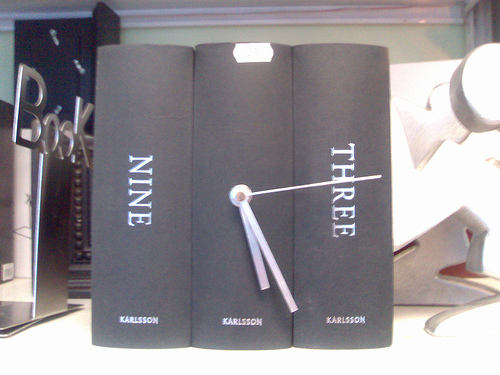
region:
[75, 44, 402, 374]
the clock is black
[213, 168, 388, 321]
the time is 5:25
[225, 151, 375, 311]
the hands are silver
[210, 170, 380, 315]
the clack has hands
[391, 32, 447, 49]
the wall is green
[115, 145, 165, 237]
the nine is silver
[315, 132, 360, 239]
the three is silver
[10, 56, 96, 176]
the word book is silver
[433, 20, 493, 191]
the light is bright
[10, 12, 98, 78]
the picture frame is backwards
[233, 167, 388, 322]
the hands of a clock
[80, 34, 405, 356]
the face of a clock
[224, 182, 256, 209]
the center of a clock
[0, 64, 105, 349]
a metal book end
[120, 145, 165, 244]
the nine on the clock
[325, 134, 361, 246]
the three on the clock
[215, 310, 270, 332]
the brand of the clock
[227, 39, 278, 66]
a metal tag on the clock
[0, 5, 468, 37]
white trim on the wall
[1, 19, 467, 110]
a green wall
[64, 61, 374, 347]
a book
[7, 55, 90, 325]
a silver book holder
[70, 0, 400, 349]
a clock on a shelf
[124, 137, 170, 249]
silver writing on a clock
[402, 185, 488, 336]
a dark spot next to a clock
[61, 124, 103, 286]
black beads on a shelf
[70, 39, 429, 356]
a black clock with silver hands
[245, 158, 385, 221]
a silver second hand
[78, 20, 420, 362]
a black clock on the shelf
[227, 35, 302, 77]
a white spot on the clock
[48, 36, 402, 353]
A clock that looks like a stack of books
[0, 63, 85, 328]
Silver book-stand with the word Book on the top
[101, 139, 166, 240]
Silver inlaid word nine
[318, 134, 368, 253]
Silver inlaid word three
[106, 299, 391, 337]
Three Silver inlaid names of Karlsson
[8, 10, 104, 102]
Possible black Cabinet in the background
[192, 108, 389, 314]
Silver colored minute hands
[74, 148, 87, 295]
Possible picture frame in the background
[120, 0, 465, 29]
White trim around the ceiling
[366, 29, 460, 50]
Extremely light green wall color